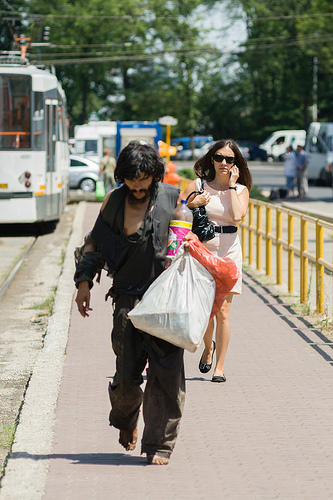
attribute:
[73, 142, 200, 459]
man — homeless, barefoot, walking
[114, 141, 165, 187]
hair — dark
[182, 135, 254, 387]
woman — well dressed, walking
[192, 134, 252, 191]
hair — dark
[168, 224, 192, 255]
label — purple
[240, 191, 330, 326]
railing — yellow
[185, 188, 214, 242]
purse — black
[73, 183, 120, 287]
sleeve — torn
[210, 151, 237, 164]
sunglasses — dark, black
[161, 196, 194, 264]
bottle — empty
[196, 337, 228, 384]
dress shoes — black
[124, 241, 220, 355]
bag — white, made of plastic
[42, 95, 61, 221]
metal doors — long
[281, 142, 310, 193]
two men — standing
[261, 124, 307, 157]
van — white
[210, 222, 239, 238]
belt — black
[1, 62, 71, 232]
bus — white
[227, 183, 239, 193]
wristwatch — black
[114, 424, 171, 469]
man's feet — dirty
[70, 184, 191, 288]
shirt — ripped, ripped up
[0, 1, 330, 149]
trees — green